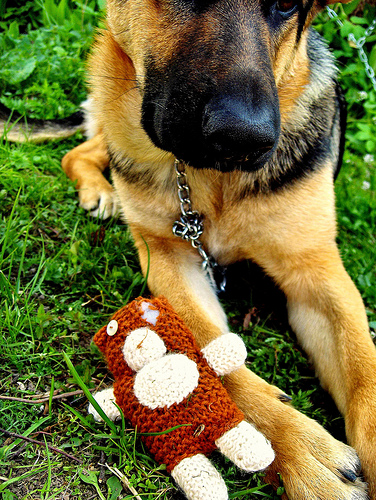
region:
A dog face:
[98, 1, 337, 173]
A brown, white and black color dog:
[29, 0, 373, 497]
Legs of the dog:
[248, 381, 373, 491]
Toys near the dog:
[59, 275, 279, 496]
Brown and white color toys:
[54, 329, 263, 497]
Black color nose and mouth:
[152, 69, 300, 183]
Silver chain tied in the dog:
[168, 160, 235, 292]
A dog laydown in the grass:
[12, 6, 375, 491]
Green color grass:
[6, 145, 75, 416]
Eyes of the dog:
[270, 1, 314, 28]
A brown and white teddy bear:
[87, 293, 275, 499]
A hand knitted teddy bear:
[85, 296, 276, 499]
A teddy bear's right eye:
[105, 316, 120, 335]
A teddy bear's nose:
[123, 328, 165, 369]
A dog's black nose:
[204, 94, 278, 163]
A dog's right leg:
[64, 152, 120, 220]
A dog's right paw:
[225, 374, 368, 498]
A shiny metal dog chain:
[172, 158, 226, 290]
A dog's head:
[103, 0, 346, 172]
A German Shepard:
[62, 1, 374, 498]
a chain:
[166, 175, 210, 254]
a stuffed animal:
[86, 316, 234, 465]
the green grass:
[18, 260, 88, 345]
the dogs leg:
[276, 257, 374, 370]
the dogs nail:
[336, 448, 359, 485]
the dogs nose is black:
[207, 96, 275, 159]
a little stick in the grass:
[15, 385, 68, 411]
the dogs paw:
[84, 168, 121, 228]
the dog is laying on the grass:
[73, 26, 357, 303]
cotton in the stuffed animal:
[132, 306, 169, 332]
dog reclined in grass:
[56, 8, 365, 254]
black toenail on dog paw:
[329, 454, 360, 488]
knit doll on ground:
[95, 281, 259, 493]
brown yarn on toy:
[162, 390, 234, 445]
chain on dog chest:
[162, 163, 220, 270]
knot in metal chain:
[169, 202, 216, 246]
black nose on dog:
[199, 102, 294, 164]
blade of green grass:
[46, 346, 120, 445]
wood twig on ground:
[7, 428, 90, 467]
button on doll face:
[104, 311, 127, 342]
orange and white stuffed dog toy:
[78, 290, 276, 498]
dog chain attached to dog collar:
[150, 129, 270, 313]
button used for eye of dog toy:
[104, 317, 122, 336]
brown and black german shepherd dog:
[0, 0, 374, 498]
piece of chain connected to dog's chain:
[316, 0, 374, 110]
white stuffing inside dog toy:
[136, 296, 167, 328]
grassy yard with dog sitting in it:
[0, 0, 374, 498]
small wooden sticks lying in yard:
[0, 285, 186, 498]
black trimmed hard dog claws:
[274, 382, 360, 488]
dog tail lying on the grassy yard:
[0, 80, 100, 162]